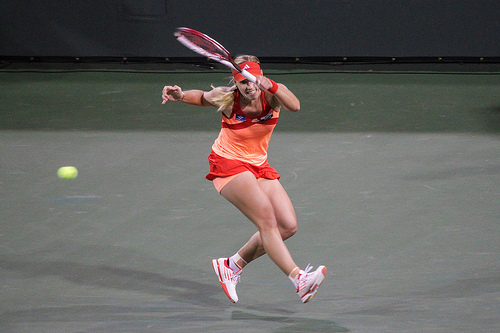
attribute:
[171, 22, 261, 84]
racket — tennis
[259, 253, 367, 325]
shoe — white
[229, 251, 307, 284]
socks — white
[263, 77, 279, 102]
band — orange, wrist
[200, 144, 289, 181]
skirt — orange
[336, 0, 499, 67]
tarp — game, riveted, black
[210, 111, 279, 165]
shirt — peach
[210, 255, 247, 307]
shoe — tennis, white, orange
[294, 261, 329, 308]
shoe — tennis, white, orange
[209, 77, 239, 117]
hair — blonde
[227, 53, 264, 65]
hair — blonde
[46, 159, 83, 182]
tennis ball — green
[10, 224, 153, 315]
ground — concrete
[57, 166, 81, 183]
tennis ball — bright yellow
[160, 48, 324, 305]
player — tennis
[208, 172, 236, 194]
shorts — peach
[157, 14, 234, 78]
racket — tennis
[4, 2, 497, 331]
game — tennis, aggressive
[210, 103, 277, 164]
top — peach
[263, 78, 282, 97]
wristband — orange